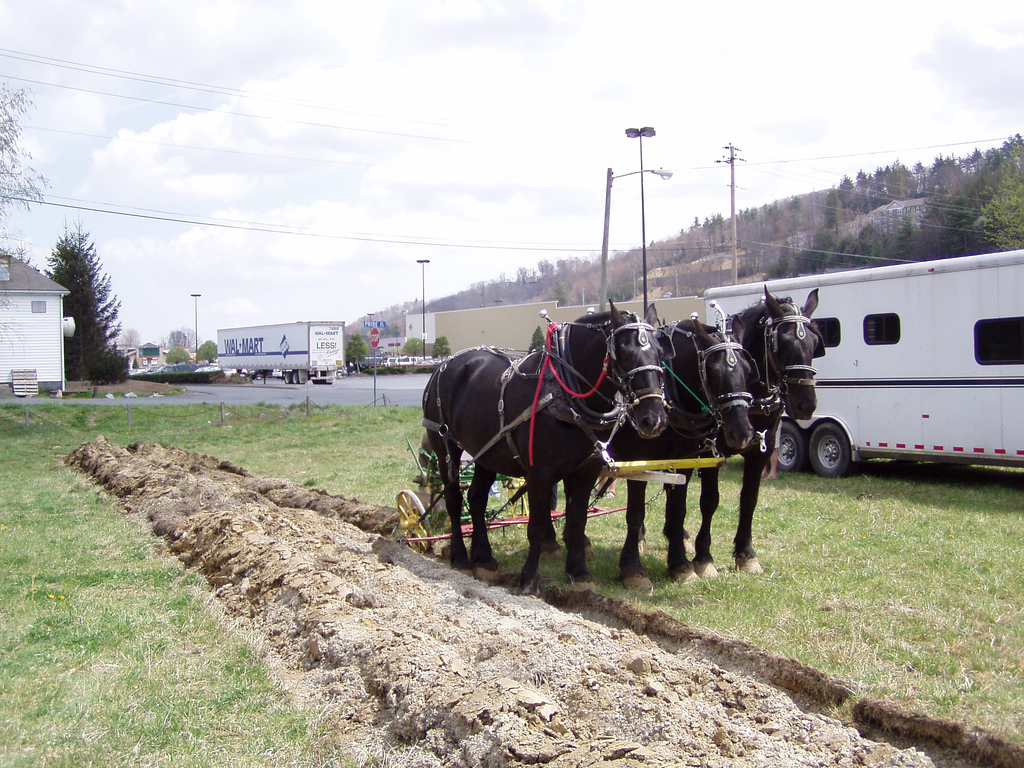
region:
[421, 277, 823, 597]
the horses are standing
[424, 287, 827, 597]
the horses are standing together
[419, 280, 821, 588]
the horses are black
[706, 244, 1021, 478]
the long trailer is white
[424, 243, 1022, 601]
the horses near the long trailer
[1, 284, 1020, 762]
the horses standing on the grassy area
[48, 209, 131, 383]
the pine tree is thick and tall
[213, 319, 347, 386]
the blue letters spell out wal-mart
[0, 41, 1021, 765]
the power lines above the ground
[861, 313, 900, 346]
the black window is small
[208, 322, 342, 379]
Walmart truck container behind the horses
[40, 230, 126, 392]
green tree by the building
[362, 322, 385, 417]
stop sign at the corner of the street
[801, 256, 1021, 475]
white horse trailer by the horses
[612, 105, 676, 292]
street light behind the horses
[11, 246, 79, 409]
white building behind the horses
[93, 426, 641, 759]
plowed earth by the horses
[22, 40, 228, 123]
power lines in the sky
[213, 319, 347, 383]
a long semi trailer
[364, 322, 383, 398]
a red and white traffic sign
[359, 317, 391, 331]
a blue and white street sign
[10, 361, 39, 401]
a wood pallet leaning on a building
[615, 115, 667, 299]
a tall street light on a post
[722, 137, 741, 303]
a wood electrical pole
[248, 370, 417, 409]
a paved parking lot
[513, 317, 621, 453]
a red rope on a horse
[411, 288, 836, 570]
three black horses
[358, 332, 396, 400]
a red and white traffic sign on a post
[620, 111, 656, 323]
a security light on a pole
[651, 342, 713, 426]
a green rope on a horse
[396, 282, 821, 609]
draft horses pulling a plow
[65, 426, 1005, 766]
tilled up earth next to grass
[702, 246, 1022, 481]
horse trailer for several horses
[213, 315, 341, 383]
walmart semi trailer going down the road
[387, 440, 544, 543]
plow that gets pulled behind horses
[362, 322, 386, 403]
stop sign on a street corner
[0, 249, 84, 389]
white building with gray roof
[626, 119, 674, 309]
black street light post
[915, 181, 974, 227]
green leaves on the tree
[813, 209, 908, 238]
green leaves on the tree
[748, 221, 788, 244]
green leaves on the tree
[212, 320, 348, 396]
a parked tractor trailer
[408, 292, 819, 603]
three black horses in a row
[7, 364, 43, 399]
a wood pallet leaned against a building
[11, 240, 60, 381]
a white building with a grey roof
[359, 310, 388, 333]
a blue and white street sign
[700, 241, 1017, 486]
a white horse trailer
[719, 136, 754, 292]
a wood electrical pole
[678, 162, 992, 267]
a hillside covered with trees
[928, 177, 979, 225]
green leaves on the tree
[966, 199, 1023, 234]
green leaves on the tree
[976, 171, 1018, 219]
green leaves on the tree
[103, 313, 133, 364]
green leaves on the tree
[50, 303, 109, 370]
green leaves on the tree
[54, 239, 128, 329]
green leaves on the tree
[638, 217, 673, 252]
green leaves on the tree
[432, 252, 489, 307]
green leaves on the tree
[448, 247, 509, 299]
green leaves on the tree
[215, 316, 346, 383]
large white walmart truck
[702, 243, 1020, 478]
large white horse trailer